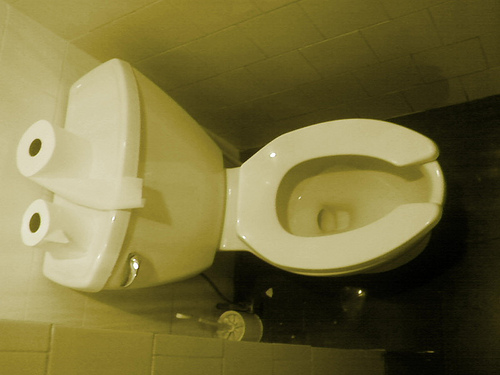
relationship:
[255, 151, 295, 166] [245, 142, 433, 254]
glare on bowl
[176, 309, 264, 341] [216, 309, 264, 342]
brush in container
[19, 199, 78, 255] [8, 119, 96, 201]
roll of paper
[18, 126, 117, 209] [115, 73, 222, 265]
paper on top toilet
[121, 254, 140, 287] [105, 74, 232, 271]
handle on toilet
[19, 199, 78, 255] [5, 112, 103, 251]
roll of paper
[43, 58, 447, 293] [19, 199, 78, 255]
toilet with roll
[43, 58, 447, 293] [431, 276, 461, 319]
toilet on the floor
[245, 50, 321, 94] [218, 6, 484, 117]
tile on the wall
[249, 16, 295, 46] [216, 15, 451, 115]
tile on the wall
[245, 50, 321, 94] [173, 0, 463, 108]
tile on the wall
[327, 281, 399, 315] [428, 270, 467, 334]
glare on the floor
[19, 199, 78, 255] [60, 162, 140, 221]
roll of paper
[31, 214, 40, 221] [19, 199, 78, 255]
roll of  the roll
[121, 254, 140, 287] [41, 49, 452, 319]
handle to flush toilet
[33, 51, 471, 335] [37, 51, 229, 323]
toilet has tank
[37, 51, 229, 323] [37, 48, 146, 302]
tank has lid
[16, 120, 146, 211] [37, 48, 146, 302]
paper on lid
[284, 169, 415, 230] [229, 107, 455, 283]
water in toilet bowl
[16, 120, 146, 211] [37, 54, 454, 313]
paper on top of bowl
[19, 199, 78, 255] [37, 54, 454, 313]
roll on top of bowl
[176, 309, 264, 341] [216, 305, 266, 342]
brush in container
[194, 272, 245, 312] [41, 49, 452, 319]
water line to toilet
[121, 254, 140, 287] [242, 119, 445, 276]
handle on bowl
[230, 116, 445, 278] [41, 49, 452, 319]
seat of toilet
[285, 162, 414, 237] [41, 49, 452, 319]
water in toilet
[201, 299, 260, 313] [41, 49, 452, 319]
pipe going to toilet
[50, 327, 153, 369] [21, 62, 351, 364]
brick in a wall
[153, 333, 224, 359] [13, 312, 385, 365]
brick in a wall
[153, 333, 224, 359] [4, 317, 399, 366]
brick in a wall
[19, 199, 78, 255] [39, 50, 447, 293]
roll on the toilet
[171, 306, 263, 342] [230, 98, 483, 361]
brush on the floor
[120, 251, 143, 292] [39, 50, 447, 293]
handle on the toilet